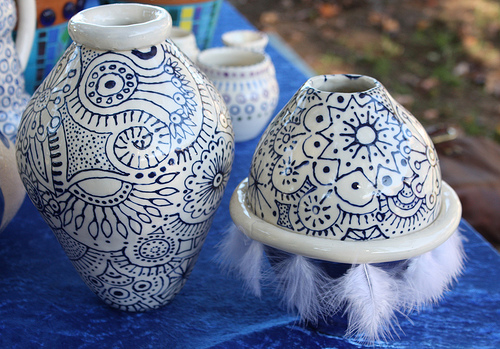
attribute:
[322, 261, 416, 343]
feather — white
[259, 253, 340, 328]
feather — white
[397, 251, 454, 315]
feather — white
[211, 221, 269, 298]
feather — white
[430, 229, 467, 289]
feather — white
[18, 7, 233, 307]
vase — white, blue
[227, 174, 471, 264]
whitering — white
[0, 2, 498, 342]
tablecloth — blue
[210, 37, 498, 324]
pot — white, black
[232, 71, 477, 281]
vase — small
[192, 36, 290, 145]
vase — small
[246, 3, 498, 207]
ground — brown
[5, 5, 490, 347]
table surface — blue, shiny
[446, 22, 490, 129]
background — green, brown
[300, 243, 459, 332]
feathers — white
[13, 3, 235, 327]
vase — ceramic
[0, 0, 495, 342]
table cloth — blue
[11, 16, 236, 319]
pot — black, white, moulded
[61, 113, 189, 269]
designs — blue, white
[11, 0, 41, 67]
handle — white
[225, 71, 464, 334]
item — ceramic